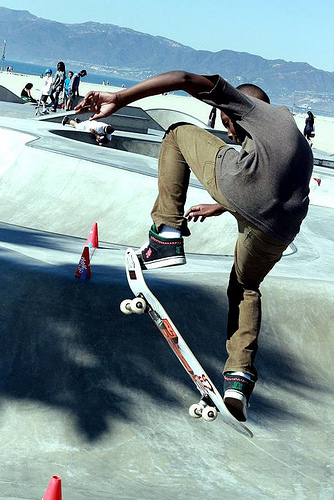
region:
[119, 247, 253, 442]
White skateboard with white wheels in midair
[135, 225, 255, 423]
Black shoes with white rubber soles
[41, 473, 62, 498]
Top of a red safety cone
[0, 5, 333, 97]
A mountain range with small patches of snow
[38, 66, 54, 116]
Person in a white t shirt wearing a helmet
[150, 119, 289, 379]
Olive colored jeans with back pockets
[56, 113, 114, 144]
Person on their stomach looking into a large hole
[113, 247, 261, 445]
Board is in mid air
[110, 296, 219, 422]
Wheels on board are white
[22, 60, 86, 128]
Group of people gathered together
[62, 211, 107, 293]
2 pylons on the concrete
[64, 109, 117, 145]
Boy in white shirt laying on stomach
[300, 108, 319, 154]
Girl with long hair walking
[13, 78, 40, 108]
Person sitting on the concrete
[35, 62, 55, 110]
Young skater wearing helmet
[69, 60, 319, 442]
Skater performing trick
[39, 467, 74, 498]
Pylon seen partially at bottom of image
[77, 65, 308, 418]
black young boy skateboarding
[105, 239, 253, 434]
skateboard boy is on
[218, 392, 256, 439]
front of the skateboard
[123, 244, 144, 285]
back of the skateboard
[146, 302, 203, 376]
middle of the skateboard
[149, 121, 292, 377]
brown pants the boy is wearing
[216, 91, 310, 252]
blue shirt the boy is wearing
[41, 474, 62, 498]
red cone sitting on the concrete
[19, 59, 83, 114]
People in the background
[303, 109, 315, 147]
lady walking with a purse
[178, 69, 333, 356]
this is a skateboarder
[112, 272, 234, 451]
the skateboard is designed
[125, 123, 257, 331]
this is a boy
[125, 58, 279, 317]
the boy has dark skin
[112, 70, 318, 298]
the boy is black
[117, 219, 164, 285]
the shoes are orange and black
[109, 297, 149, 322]
the wheels are white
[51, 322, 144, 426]
the ramp is light gray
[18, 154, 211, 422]
this is a skatepark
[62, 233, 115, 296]
these are orange cones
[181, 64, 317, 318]
boy wearing gray shirt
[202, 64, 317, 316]
boy wearing brown pants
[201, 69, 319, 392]
boy wearing black shoes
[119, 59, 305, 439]
boy on a skate board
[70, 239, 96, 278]
cone on a ramp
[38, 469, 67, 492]
cone on a ramp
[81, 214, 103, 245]
cone on a ramp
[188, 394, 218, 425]
wheel on a skate board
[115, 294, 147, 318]
wheel on a skate board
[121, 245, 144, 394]
skate board in the air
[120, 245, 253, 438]
a white printed skateboard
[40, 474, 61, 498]
a red cone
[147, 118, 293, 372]
a pair of men's jeans